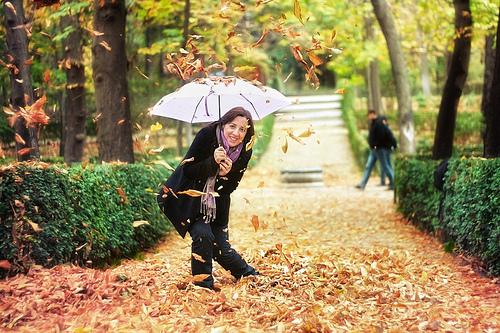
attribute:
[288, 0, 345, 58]
leaves — green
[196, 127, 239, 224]
scarf — light , purple, silk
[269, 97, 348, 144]
steps — concrete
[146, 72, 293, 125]
white umbrella — over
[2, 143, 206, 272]
bushes — green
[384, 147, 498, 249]
bushes — green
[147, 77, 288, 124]
umbrella — white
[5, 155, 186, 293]
hedges — trimmed 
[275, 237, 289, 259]
leaf — brown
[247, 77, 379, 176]
bridge — wooden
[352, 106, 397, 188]
man — wearing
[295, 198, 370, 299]
leaves — piled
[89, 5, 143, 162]
tree trunk — brown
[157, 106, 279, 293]
woman — wearing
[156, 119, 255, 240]
coat — black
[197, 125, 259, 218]
scarf — purple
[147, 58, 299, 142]
umbrella — white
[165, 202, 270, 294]
legs — crossed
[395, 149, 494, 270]
hedge — green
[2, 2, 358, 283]
leaves — falling, gold, lightweight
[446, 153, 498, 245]
hedges — manicured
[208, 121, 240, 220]
scarf — purple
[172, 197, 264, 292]
pants — black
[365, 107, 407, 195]
people — walking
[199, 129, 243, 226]
scarf — purple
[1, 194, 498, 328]
dead leaves — brown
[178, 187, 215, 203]
leaf — orange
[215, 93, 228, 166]
handle — black